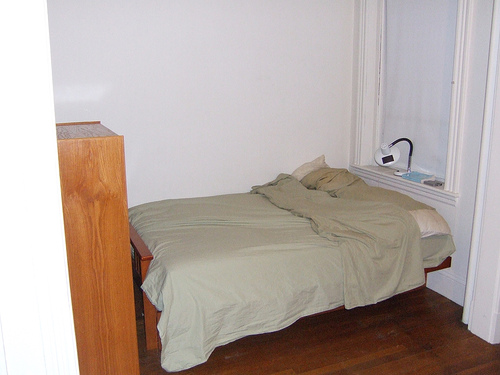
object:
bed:
[129, 154, 455, 372]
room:
[0, 1, 499, 374]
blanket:
[127, 173, 425, 371]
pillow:
[410, 207, 452, 238]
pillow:
[291, 154, 330, 181]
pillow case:
[334, 178, 436, 210]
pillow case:
[300, 164, 362, 196]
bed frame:
[128, 222, 451, 350]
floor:
[134, 277, 499, 374]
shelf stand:
[55, 121, 141, 374]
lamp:
[374, 137, 413, 176]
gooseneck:
[389, 137, 414, 172]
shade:
[378, 0, 458, 181]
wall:
[47, 0, 355, 210]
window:
[351, 0, 475, 205]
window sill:
[350, 162, 461, 207]